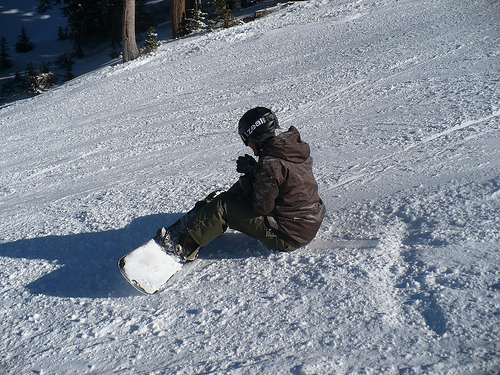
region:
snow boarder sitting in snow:
[98, 94, 332, 303]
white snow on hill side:
[13, 125, 53, 155]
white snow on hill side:
[338, 292, 366, 323]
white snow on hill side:
[252, 303, 297, 340]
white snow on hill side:
[391, 263, 448, 323]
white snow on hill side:
[37, 308, 72, 339]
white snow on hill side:
[362, 132, 422, 212]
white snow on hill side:
[329, 51, 355, 78]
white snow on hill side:
[120, 75, 173, 140]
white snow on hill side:
[56, 124, 100, 168]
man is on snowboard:
[155, 97, 326, 264]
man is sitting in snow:
[152, 100, 324, 259]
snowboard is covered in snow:
[109, 197, 201, 292]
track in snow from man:
[303, 232, 378, 266]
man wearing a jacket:
[231, 125, 331, 252]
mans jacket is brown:
[235, 121, 333, 243]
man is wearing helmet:
[231, 103, 281, 154]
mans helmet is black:
[229, 100, 279, 146]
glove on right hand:
[229, 151, 261, 178]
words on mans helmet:
[243, 116, 265, 136]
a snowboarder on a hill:
[138, 87, 339, 272]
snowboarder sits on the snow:
[115, 100, 342, 275]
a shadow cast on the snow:
[9, 192, 139, 313]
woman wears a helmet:
[224, 98, 302, 183]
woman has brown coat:
[154, 93, 334, 273]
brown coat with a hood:
[211, 128, 327, 248]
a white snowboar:
[111, 206, 185, 300]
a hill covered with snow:
[3, 9, 498, 361]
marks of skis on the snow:
[341, 45, 486, 185]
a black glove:
[226, 148, 259, 184]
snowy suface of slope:
[6, 3, 497, 372]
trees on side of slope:
[118, 2, 220, 57]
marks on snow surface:
[4, 3, 497, 372]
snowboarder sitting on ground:
[118, 103, 328, 296]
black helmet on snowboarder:
[237, 105, 279, 149]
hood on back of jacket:
[265, 124, 309, 163]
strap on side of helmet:
[238, 105, 278, 148]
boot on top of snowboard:
[151, 223, 192, 266]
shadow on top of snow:
[4, 209, 258, 298]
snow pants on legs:
[185, 193, 290, 255]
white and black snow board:
[120, 187, 233, 291]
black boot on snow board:
[160, 229, 197, 261]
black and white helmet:
[236, 107, 281, 141]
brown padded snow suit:
[189, 155, 326, 252]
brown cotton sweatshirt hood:
[266, 126, 311, 163]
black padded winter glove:
[236, 153, 258, 174]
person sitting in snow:
[121, 108, 326, 295]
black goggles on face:
[238, 133, 248, 143]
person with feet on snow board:
[123, 106, 330, 293]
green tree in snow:
[15, 25, 33, 52]